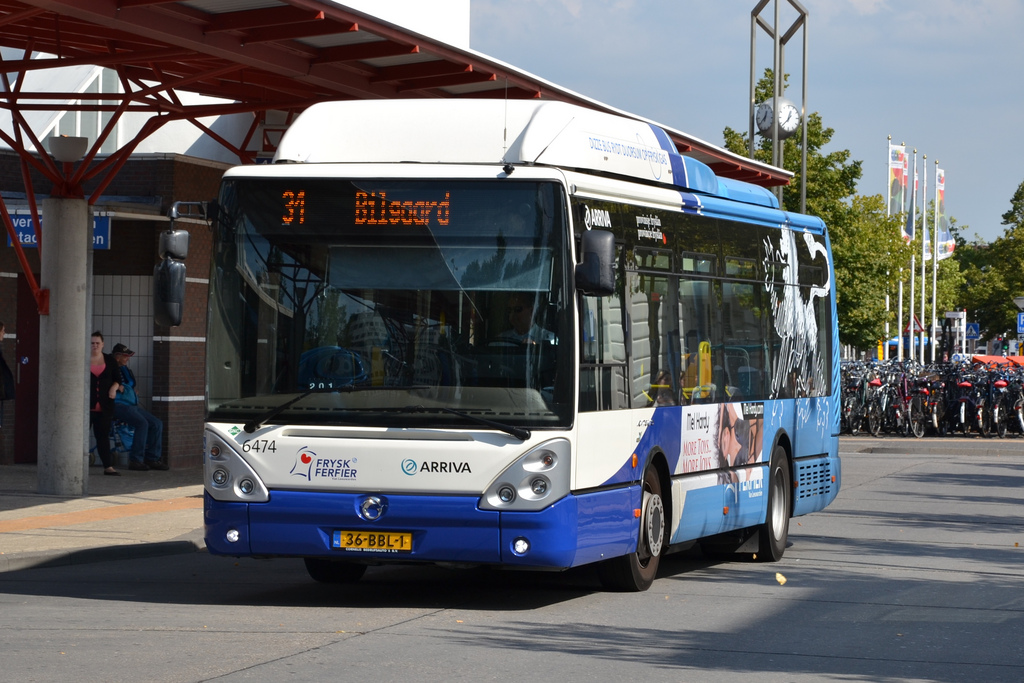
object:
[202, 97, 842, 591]
bus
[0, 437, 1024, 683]
road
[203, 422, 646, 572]
trim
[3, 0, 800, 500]
building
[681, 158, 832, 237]
trim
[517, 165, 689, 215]
trim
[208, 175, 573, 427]
window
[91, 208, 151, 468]
wall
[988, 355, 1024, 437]
motorcycle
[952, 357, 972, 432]
motorcycle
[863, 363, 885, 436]
motorcycle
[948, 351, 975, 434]
motorcycle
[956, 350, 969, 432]
motorcycle